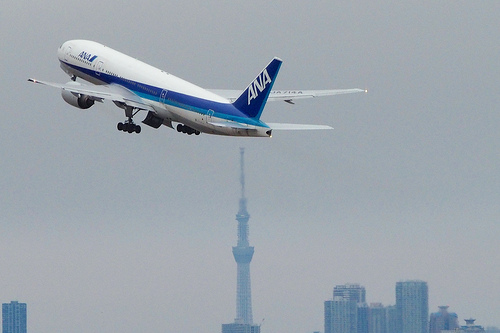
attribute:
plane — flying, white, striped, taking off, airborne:
[26, 38, 372, 142]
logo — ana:
[74, 46, 100, 64]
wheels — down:
[118, 119, 199, 134]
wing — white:
[26, 75, 138, 113]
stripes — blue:
[67, 57, 285, 121]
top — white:
[58, 40, 232, 99]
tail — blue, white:
[231, 56, 297, 142]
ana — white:
[247, 67, 273, 104]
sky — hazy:
[0, 1, 499, 330]